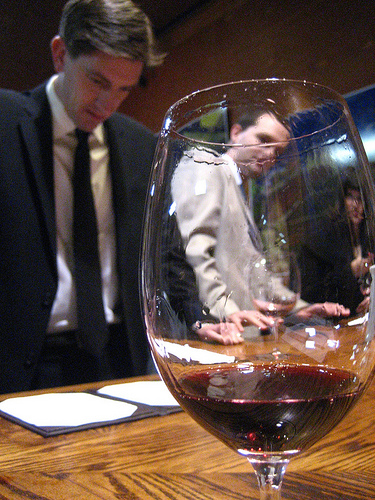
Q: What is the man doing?
A: Reading the menu.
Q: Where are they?
A: In a restaurant.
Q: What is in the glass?
A: Red wine.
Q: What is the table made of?
A: Wood.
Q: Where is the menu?
A: On the table.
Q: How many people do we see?
A: Three.